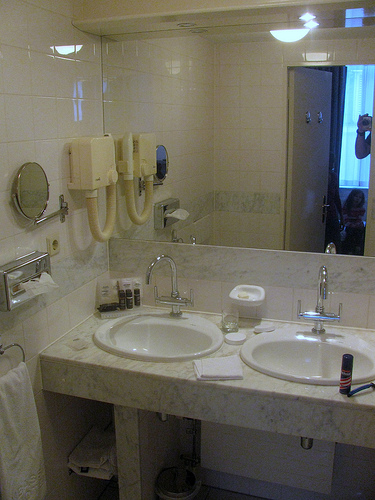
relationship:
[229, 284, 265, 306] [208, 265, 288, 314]
dish on wall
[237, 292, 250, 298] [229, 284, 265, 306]
soap on dish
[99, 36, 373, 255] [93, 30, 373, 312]
mirror on wall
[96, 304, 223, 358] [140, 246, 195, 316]
sink with faucet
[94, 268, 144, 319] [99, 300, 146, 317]
toiletries on tray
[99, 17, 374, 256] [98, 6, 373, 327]
mirror on wall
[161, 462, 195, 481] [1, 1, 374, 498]
can in bathroom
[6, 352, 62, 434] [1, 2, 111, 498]
towel hanging from wall